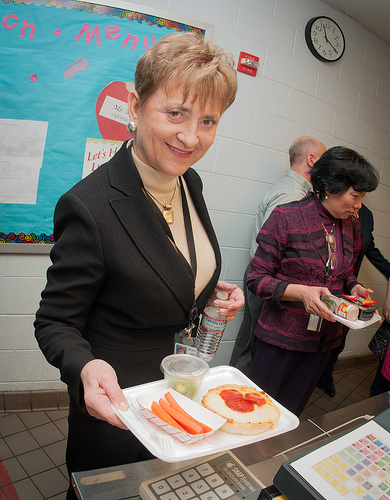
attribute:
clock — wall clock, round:
[303, 14, 346, 65]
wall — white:
[0, 43, 389, 351]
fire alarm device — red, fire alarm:
[234, 51, 260, 78]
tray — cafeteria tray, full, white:
[108, 363, 303, 465]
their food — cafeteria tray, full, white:
[316, 293, 385, 332]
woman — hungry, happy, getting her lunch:
[33, 30, 247, 498]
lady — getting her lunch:
[242, 145, 380, 421]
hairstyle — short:
[133, 33, 239, 116]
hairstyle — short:
[308, 146, 380, 205]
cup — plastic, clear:
[158, 352, 211, 400]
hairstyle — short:
[285, 137, 320, 170]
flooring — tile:
[0, 361, 383, 499]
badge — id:
[173, 341, 198, 358]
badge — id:
[305, 313, 324, 335]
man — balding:
[227, 136, 328, 375]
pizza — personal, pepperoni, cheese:
[199, 383, 282, 436]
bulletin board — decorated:
[0, 1, 216, 254]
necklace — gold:
[141, 182, 178, 229]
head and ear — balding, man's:
[287, 135, 329, 185]